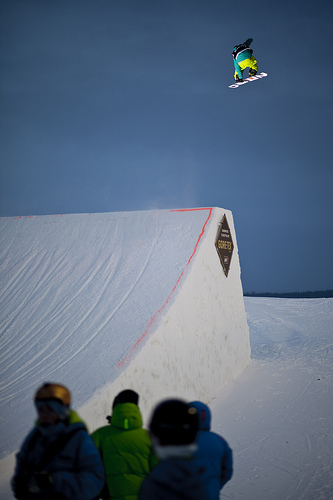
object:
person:
[231, 36, 259, 84]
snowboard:
[227, 70, 268, 90]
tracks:
[0, 220, 170, 411]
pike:
[0, 204, 251, 500]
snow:
[204, 296, 332, 500]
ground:
[204, 296, 333, 500]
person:
[86, 387, 162, 500]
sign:
[214, 211, 234, 279]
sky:
[0, 0, 333, 297]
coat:
[88, 401, 162, 499]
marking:
[113, 206, 213, 371]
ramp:
[0, 207, 219, 461]